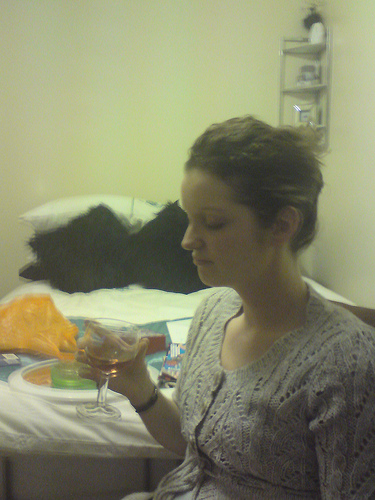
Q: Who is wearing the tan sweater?
A: The woman.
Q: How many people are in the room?
A: One.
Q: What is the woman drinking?
A: Wine.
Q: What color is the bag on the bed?
A: Yellow.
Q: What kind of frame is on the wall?
A: A picture frame.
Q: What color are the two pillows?
A: Black.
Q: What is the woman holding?
A: Glass.